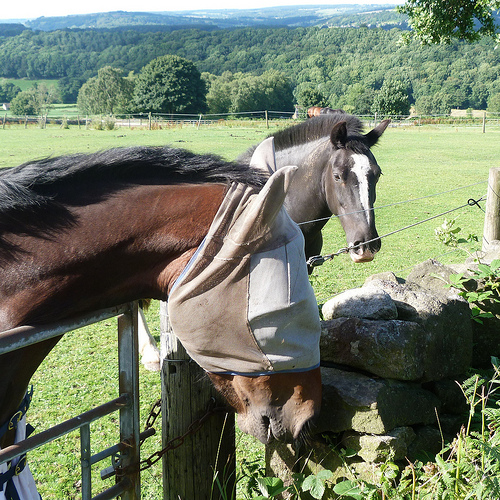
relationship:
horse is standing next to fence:
[223, 109, 393, 269] [6, 258, 416, 499]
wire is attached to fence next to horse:
[302, 195, 489, 273] [0, 160, 500, 497]